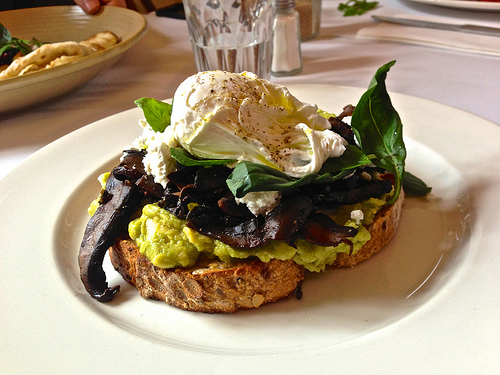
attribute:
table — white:
[9, 19, 493, 136]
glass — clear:
[176, 1, 258, 86]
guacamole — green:
[91, 171, 373, 271]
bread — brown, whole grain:
[94, 178, 405, 316]